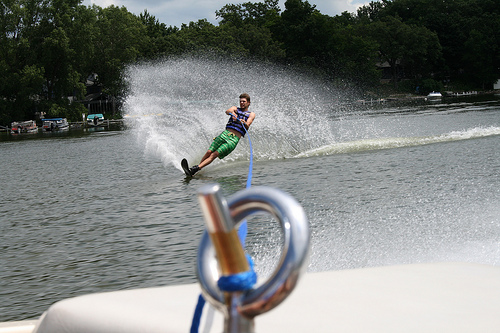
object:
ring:
[192, 183, 312, 320]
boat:
[39, 265, 499, 332]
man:
[178, 93, 258, 182]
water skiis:
[177, 155, 200, 182]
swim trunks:
[205, 127, 239, 161]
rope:
[234, 147, 257, 181]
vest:
[226, 107, 253, 138]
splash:
[157, 64, 235, 102]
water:
[435, 144, 500, 205]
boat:
[83, 110, 107, 128]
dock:
[105, 110, 124, 133]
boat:
[39, 114, 71, 133]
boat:
[7, 115, 38, 136]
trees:
[386, 0, 419, 92]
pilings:
[82, 111, 87, 123]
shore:
[343, 93, 420, 115]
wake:
[356, 128, 498, 156]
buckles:
[234, 113, 246, 130]